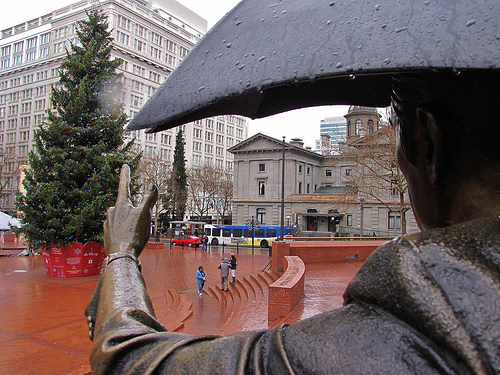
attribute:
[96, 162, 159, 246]
hand — bronze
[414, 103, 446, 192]
ear — bronze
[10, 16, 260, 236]
building — large,  tall, white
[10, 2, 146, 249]
pine tree — large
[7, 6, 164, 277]
tree — large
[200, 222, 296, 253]
bus — white, blue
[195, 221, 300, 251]
bus — blue, white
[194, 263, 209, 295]
person — walking 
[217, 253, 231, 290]
person — walking 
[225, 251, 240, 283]
person — walking 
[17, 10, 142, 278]
tree — bottom, red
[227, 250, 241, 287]
woman — standing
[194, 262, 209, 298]
woman — in mostly blue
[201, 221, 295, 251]
bus — large, blue, white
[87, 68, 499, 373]
metal statue — large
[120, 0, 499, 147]
black umbrella — large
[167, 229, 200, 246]
car — red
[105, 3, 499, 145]
umbrella — large, black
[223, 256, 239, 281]
coat — grey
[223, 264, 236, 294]
pants — tan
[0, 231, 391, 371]
area — large, wide red, bricked